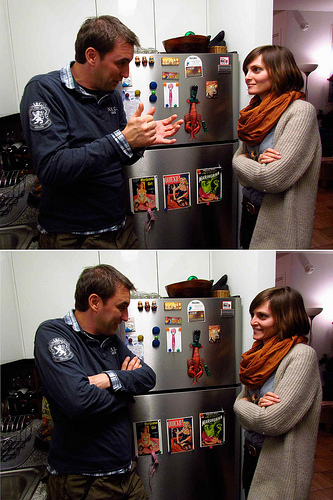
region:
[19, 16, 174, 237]
The man is gesturing with his hands.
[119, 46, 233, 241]
Magnets are all over the fridge.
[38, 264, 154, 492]
The man has his arms crossed.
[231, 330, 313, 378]
The woman is wearing a scarf.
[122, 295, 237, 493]
The fridge is made from stainless steel.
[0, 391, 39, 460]
A dish rack.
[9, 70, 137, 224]
The man is wearing a blue shirt.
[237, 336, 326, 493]
The woman is wearing a sand colored cardigan.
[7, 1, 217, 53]
The cabinets are white.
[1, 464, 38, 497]
The sink.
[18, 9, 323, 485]
Two different views of a couple.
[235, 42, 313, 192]
A woman with dark hair.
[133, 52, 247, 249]
A silver refrigerator.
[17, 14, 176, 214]
A man in a long sleeve top.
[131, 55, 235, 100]
Magnets on a refrigerator door.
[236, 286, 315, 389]
Brown scarf around woman's neck.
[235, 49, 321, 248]
A long sleeve grey sweater.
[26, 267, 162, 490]
A man with his arms crossed.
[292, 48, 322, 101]
A light in behind the woman.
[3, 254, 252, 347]
White kitchen cabinets.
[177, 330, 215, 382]
magnetic lobster on the silver fridge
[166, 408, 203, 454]
picture on the silver fridge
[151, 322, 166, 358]
clipping magnets on the silver fridge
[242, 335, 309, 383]
burnt orange infinity scarf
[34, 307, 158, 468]
man wearing a dark blue sweater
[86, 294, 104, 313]
man's ear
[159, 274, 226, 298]
basket on top of fridge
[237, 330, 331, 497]
woman wearing a long sweater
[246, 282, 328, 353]
woman with short brown hair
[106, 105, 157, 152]
thumbs up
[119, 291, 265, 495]
STAINLESS STEEL REFRIGERATOR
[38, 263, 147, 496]
A MAN STANDING NEXT TO A REFIGERATOR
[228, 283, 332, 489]
A WOMAN WITH HER ARMS CROSSED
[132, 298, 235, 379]
REFRIGERATOR MAGNETS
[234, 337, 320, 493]
A WOMAN'S GRAY SWEATER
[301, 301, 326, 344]
A FLOOR LAMP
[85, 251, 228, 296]
WHITE KITCHEN CABINETS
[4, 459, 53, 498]
A KITCHEN SINK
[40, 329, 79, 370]
A PATCH ON A MAN'S SHIRT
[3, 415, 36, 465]
A METAL DISH STRAINER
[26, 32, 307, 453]
similar photographs of man and woman in front of refrigerator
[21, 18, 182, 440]
man's hands in different position in two photographs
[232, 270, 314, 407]
woman wearing loose brown scarf around neck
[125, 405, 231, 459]
line of comic-book pictures on refrigerator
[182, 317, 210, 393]
red lobster hanging from upper door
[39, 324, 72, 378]
blue and white patch on man's sleeve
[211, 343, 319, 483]
long grey sweater with ribbing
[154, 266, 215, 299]
brown container with green object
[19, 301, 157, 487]
plaid fabric showing on man's neck, wrist and waist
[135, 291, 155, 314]
three similarly-shaped magnets on top of door